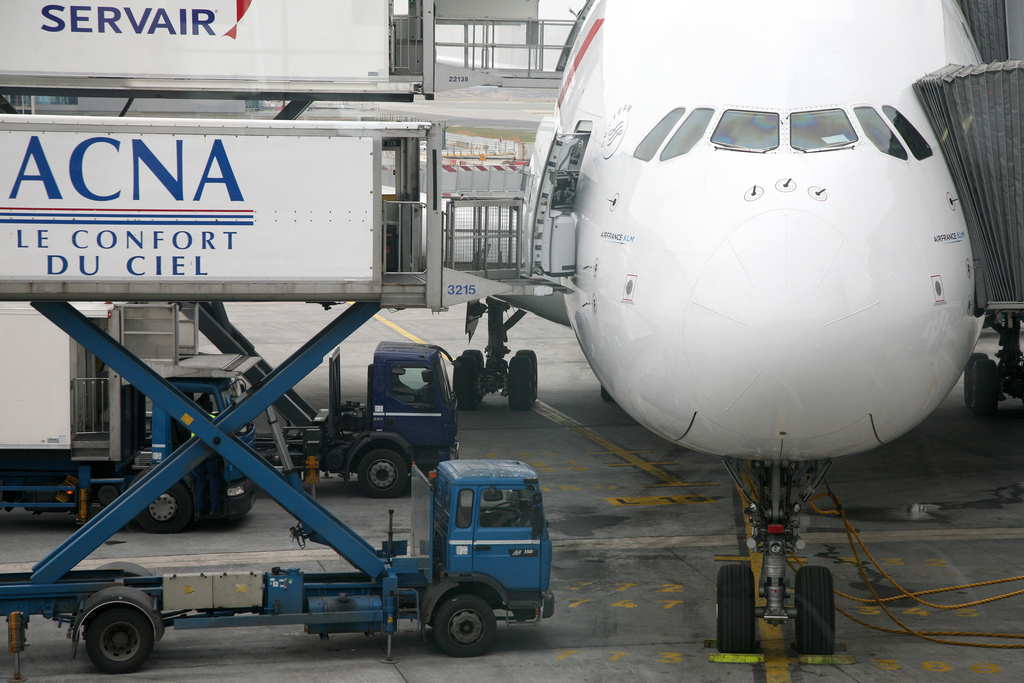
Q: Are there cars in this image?
A: No, there are no cars.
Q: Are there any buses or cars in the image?
A: No, there are no cars or buses.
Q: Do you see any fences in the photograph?
A: No, there are no fences.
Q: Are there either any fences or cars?
A: No, there are no fences or cars.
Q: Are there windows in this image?
A: Yes, there is a window.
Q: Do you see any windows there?
A: Yes, there is a window.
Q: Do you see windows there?
A: Yes, there is a window.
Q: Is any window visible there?
A: Yes, there is a window.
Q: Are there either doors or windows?
A: Yes, there is a window.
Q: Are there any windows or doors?
A: Yes, there is a window.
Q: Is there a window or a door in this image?
A: Yes, there is a window.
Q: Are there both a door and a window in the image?
A: Yes, there are both a window and a door.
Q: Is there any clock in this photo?
A: No, there are no clocks.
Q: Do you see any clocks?
A: No, there are no clocks.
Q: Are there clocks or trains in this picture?
A: No, there are no clocks or trains.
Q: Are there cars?
A: No, there are no cars.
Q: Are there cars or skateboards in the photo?
A: No, there are no cars or skateboards.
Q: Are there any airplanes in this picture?
A: Yes, there is an airplane.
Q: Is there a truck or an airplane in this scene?
A: Yes, there is an airplane.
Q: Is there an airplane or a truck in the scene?
A: Yes, there is an airplane.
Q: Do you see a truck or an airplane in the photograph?
A: Yes, there is an airplane.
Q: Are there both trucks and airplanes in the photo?
A: Yes, there are both an airplane and a truck.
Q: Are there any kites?
A: No, there are no kites.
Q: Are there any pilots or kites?
A: No, there are no kites or pilots.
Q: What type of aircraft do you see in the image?
A: The aircraft is an airplane.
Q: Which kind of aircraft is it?
A: The aircraft is an airplane.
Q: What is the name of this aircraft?
A: That is an airplane.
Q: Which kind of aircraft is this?
A: That is an airplane.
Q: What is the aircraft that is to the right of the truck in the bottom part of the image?
A: The aircraft is an airplane.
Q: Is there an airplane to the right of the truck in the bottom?
A: Yes, there is an airplane to the right of the truck.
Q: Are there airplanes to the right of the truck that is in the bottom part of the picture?
A: Yes, there is an airplane to the right of the truck.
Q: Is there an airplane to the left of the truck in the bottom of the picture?
A: No, the airplane is to the right of the truck.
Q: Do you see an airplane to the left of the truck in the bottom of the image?
A: No, the airplane is to the right of the truck.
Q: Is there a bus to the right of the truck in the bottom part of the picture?
A: No, there is an airplane to the right of the truck.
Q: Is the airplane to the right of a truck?
A: Yes, the airplane is to the right of a truck.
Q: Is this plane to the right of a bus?
A: No, the plane is to the right of a truck.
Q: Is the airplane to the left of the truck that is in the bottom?
A: No, the airplane is to the right of the truck.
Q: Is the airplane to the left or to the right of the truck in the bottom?
A: The airplane is to the right of the truck.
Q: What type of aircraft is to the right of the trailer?
A: The aircraft is an airplane.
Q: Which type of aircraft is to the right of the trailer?
A: The aircraft is an airplane.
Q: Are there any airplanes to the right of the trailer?
A: Yes, there is an airplane to the right of the trailer.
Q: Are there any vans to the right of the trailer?
A: No, there is an airplane to the right of the trailer.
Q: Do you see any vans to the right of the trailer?
A: No, there is an airplane to the right of the trailer.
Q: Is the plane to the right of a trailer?
A: Yes, the plane is to the right of a trailer.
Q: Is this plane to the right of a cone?
A: No, the plane is to the right of a trailer.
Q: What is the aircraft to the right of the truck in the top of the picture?
A: The aircraft is an airplane.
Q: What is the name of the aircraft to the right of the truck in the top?
A: The aircraft is an airplane.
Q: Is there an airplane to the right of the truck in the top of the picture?
A: Yes, there is an airplane to the right of the truck.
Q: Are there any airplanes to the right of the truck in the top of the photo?
A: Yes, there is an airplane to the right of the truck.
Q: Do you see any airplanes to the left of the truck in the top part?
A: No, the airplane is to the right of the truck.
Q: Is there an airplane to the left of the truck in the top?
A: No, the airplane is to the right of the truck.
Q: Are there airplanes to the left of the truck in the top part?
A: No, the airplane is to the right of the truck.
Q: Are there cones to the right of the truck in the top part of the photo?
A: No, there is an airplane to the right of the truck.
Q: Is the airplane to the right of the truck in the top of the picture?
A: Yes, the airplane is to the right of the truck.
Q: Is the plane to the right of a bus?
A: No, the plane is to the right of the truck.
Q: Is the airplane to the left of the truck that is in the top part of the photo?
A: No, the airplane is to the right of the truck.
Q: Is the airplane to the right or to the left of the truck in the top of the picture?
A: The airplane is to the right of the truck.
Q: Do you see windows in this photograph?
A: Yes, there is a window.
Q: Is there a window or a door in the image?
A: Yes, there is a window.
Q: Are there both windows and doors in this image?
A: Yes, there are both a window and a door.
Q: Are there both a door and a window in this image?
A: Yes, there are both a window and a door.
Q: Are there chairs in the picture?
A: No, there are no chairs.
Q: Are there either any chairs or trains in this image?
A: No, there are no chairs or trains.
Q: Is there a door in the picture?
A: Yes, there is a door.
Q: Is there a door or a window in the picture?
A: Yes, there is a door.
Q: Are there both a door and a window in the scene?
A: Yes, there are both a door and a window.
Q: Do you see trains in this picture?
A: No, there are no trains.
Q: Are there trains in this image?
A: No, there are no trains.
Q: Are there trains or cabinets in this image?
A: No, there are no trains or cabinets.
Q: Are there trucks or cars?
A: Yes, there is a truck.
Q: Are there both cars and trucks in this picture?
A: No, there is a truck but no cars.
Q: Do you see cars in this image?
A: No, there are no cars.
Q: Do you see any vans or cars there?
A: No, there are no cars or vans.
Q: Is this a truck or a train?
A: This is a truck.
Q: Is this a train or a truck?
A: This is a truck.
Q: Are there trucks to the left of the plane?
A: Yes, there is a truck to the left of the plane.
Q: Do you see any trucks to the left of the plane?
A: Yes, there is a truck to the left of the plane.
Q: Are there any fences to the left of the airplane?
A: No, there is a truck to the left of the airplane.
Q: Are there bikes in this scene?
A: No, there are no bikes.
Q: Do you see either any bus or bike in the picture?
A: No, there are no bikes or buses.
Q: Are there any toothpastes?
A: No, there are no toothpastes.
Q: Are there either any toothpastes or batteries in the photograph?
A: No, there are no toothpastes or batteries.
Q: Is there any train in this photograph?
A: No, there are no trains.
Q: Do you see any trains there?
A: No, there are no trains.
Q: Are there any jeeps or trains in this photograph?
A: No, there are no trains or jeeps.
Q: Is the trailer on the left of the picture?
A: Yes, the trailer is on the left of the image.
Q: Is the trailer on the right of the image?
A: No, the trailer is on the left of the image.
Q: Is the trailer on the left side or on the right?
A: The trailer is on the left of the image.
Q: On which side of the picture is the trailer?
A: The trailer is on the left of the image.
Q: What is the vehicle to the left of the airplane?
A: The vehicle is a trailer.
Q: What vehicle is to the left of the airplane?
A: The vehicle is a trailer.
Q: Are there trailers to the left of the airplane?
A: Yes, there is a trailer to the left of the airplane.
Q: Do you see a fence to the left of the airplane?
A: No, there is a trailer to the left of the airplane.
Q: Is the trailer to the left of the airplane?
A: Yes, the trailer is to the left of the airplane.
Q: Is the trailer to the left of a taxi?
A: No, the trailer is to the left of the airplane.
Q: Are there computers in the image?
A: No, there are no computers.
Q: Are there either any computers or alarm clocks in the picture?
A: No, there are no computers or alarm clocks.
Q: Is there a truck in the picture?
A: Yes, there is a truck.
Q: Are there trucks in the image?
A: Yes, there is a truck.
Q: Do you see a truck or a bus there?
A: Yes, there is a truck.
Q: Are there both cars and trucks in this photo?
A: No, there is a truck but no cars.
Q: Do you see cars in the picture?
A: No, there are no cars.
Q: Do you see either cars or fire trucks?
A: No, there are no cars or fire trucks.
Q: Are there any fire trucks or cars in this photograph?
A: No, there are no cars or fire trucks.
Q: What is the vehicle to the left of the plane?
A: The vehicle is a truck.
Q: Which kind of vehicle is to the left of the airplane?
A: The vehicle is a truck.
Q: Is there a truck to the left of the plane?
A: Yes, there is a truck to the left of the plane.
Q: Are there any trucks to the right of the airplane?
A: No, the truck is to the left of the airplane.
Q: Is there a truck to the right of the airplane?
A: No, the truck is to the left of the airplane.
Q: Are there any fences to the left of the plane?
A: No, there is a truck to the left of the plane.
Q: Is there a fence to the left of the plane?
A: No, there is a truck to the left of the plane.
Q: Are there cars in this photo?
A: No, there are no cars.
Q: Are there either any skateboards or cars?
A: No, there are no cars or skateboards.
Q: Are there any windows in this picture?
A: Yes, there is a window.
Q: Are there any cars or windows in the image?
A: Yes, there is a window.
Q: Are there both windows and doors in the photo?
A: Yes, there are both a window and a door.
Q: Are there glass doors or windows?
A: Yes, there is a glass window.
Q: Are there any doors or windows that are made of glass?
A: Yes, the window is made of glass.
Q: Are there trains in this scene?
A: No, there are no trains.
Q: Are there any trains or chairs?
A: No, there are no trains or chairs.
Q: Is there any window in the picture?
A: Yes, there is a window.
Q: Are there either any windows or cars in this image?
A: Yes, there is a window.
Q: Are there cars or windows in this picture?
A: Yes, there is a window.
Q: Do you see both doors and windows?
A: Yes, there are both a window and doors.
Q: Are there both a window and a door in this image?
A: Yes, there are both a window and a door.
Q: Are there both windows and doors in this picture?
A: Yes, there are both a window and doors.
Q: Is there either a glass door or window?
A: Yes, there is a glass window.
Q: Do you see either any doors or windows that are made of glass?
A: Yes, the window is made of glass.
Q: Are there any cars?
A: No, there are no cars.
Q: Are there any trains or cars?
A: No, there are no cars or trains.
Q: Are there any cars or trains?
A: No, there are no cars or trains.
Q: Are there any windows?
A: Yes, there is a window.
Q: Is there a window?
A: Yes, there is a window.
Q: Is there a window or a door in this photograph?
A: Yes, there is a window.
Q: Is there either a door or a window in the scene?
A: Yes, there is a window.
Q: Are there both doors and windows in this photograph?
A: Yes, there are both a window and doors.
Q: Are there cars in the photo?
A: No, there are no cars.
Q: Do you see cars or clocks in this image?
A: No, there are no cars or clocks.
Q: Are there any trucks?
A: Yes, there is a truck.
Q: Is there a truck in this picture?
A: Yes, there is a truck.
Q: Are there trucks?
A: Yes, there is a truck.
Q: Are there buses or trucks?
A: Yes, there is a truck.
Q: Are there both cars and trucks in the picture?
A: No, there is a truck but no cars.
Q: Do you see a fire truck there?
A: No, there are no fire trucks.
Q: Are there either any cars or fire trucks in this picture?
A: No, there are no fire trucks or cars.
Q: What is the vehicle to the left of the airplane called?
A: The vehicle is a truck.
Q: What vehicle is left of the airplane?
A: The vehicle is a truck.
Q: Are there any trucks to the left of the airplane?
A: Yes, there is a truck to the left of the airplane.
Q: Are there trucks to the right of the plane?
A: No, the truck is to the left of the plane.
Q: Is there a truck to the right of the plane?
A: No, the truck is to the left of the plane.